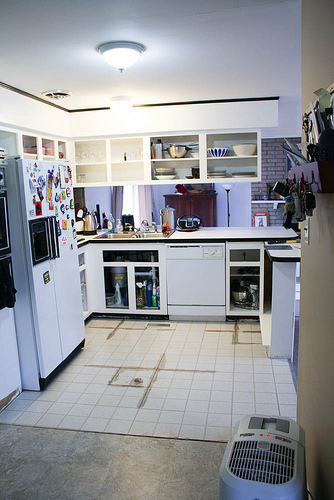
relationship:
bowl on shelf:
[161, 142, 197, 161] [150, 154, 199, 162]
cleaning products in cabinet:
[133, 280, 160, 317] [96, 244, 159, 312]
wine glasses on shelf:
[77, 146, 104, 161] [71, 138, 110, 166]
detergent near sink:
[105, 212, 116, 230] [90, 228, 173, 241]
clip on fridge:
[47, 169, 53, 176] [4, 159, 84, 391]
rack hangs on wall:
[273, 158, 333, 228] [296, 0, 333, 499]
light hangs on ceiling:
[95, 38, 145, 74] [0, 0, 302, 125]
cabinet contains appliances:
[144, 127, 200, 184] [151, 135, 199, 156]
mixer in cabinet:
[230, 281, 267, 312] [208, 233, 283, 325]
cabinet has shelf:
[208, 233, 283, 325] [229, 267, 262, 319]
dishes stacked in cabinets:
[154, 166, 178, 180] [150, 131, 257, 177]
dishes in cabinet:
[153, 165, 178, 179] [144, 132, 264, 185]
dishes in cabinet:
[207, 167, 257, 177] [144, 132, 264, 185]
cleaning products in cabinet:
[135, 280, 160, 309] [102, 249, 160, 318]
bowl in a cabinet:
[226, 140, 259, 160] [206, 133, 255, 180]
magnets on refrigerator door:
[26, 159, 78, 214] [19, 161, 86, 366]